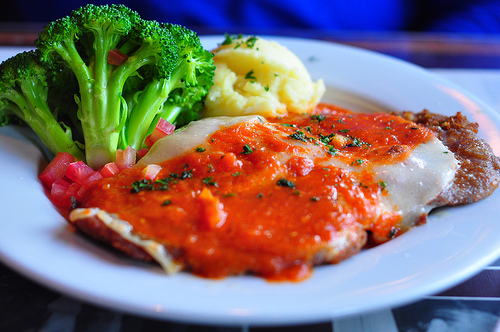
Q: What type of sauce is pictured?
A: The sauce is a dressing.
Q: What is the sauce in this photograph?
A: The sauce is a dressing.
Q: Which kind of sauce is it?
A: The sauce is a dressing.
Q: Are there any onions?
A: Yes, there are onions.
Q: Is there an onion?
A: Yes, there are onions.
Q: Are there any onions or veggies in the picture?
A: Yes, there are onions.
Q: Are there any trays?
A: No, there are no trays.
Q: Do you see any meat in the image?
A: Yes, there is meat.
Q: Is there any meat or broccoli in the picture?
A: Yes, there is meat.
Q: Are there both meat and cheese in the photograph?
A: Yes, there are both meat and cheese.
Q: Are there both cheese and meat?
A: Yes, there are both meat and cheese.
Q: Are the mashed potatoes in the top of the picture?
A: Yes, the mashed potatoes are in the top of the image.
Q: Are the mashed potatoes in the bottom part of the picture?
A: No, the mashed potatoes are in the top of the image.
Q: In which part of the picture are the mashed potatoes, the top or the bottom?
A: The mashed potatoes are in the top of the image.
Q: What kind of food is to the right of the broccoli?
A: The food is mashed potatoes.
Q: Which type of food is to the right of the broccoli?
A: The food is mashed potatoes.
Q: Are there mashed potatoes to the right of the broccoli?
A: Yes, there are mashed potatoes to the right of the broccoli.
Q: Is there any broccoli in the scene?
A: Yes, there is broccoli.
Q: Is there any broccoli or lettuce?
A: Yes, there is broccoli.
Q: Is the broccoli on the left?
A: Yes, the broccoli is on the left of the image.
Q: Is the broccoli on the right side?
A: No, the broccoli is on the left of the image.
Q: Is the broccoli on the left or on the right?
A: The broccoli is on the left of the image.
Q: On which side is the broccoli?
A: The broccoli is on the left of the image.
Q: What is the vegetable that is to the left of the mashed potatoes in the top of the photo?
A: The vegetable is broccoli.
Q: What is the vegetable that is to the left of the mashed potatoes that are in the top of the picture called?
A: The vegetable is broccoli.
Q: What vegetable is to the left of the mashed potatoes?
A: The vegetable is broccoli.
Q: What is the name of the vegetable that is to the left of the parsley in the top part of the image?
A: The vegetable is broccoli.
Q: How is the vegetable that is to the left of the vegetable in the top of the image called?
A: The vegetable is broccoli.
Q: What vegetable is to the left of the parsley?
A: The vegetable is broccoli.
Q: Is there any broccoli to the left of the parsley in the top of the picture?
A: Yes, there is broccoli to the left of the parsley.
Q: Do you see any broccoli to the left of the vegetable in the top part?
A: Yes, there is broccoli to the left of the parsley.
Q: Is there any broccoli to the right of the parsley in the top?
A: No, the broccoli is to the left of the parsley.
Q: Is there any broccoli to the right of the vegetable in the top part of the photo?
A: No, the broccoli is to the left of the parsley.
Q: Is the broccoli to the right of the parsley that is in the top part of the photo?
A: No, the broccoli is to the left of the parsley.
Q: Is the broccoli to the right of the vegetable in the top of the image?
A: No, the broccoli is to the left of the parsley.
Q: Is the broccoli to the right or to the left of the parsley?
A: The broccoli is to the left of the parsley.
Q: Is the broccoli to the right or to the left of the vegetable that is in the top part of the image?
A: The broccoli is to the left of the parsley.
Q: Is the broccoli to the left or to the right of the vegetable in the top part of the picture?
A: The broccoli is to the left of the parsley.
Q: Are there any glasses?
A: No, there are no glasses.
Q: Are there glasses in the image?
A: No, there are no glasses.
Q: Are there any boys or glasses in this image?
A: No, there are no glasses or boys.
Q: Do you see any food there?
A: Yes, there is food.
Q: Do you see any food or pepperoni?
A: Yes, there is food.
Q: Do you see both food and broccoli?
A: Yes, there are both food and broccoli.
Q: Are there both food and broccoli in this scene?
A: Yes, there are both food and broccoli.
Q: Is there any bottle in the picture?
A: No, there are no bottles.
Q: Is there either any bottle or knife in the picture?
A: No, there are no bottles or knives.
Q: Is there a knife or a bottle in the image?
A: No, there are no bottles or knives.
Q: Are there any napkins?
A: No, there are no napkins.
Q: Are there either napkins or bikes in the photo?
A: No, there are no napkins or bikes.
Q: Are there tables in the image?
A: Yes, there is a table.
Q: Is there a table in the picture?
A: Yes, there is a table.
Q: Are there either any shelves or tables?
A: Yes, there is a table.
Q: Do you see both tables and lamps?
A: No, there is a table but no lamps.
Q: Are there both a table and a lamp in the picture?
A: No, there is a table but no lamps.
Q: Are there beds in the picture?
A: No, there are no beds.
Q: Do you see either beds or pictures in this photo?
A: No, there are no beds or pictures.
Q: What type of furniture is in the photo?
A: The furniture is a table.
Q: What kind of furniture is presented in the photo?
A: The furniture is a table.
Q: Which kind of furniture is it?
A: The piece of furniture is a table.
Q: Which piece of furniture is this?
A: This is a table.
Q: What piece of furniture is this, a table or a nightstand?
A: This is a table.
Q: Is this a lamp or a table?
A: This is a table.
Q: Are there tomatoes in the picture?
A: Yes, there are tomatoes.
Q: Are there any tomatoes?
A: Yes, there are tomatoes.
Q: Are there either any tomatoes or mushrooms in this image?
A: Yes, there are tomatoes.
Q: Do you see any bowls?
A: No, there are no bowls.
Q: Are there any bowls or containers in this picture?
A: No, there are no bowls or containers.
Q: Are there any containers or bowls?
A: No, there are no bowls or containers.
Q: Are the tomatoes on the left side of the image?
A: Yes, the tomatoes are on the left of the image.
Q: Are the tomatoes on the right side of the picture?
A: No, the tomatoes are on the left of the image.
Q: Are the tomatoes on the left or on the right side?
A: The tomatoes are on the left of the image.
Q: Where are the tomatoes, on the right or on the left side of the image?
A: The tomatoes are on the left of the image.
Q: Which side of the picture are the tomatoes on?
A: The tomatoes are on the left of the image.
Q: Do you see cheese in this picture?
A: Yes, there is cheese.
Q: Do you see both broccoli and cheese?
A: Yes, there are both cheese and broccoli.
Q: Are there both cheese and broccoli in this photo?
A: Yes, there are both cheese and broccoli.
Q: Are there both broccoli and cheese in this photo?
A: Yes, there are both cheese and broccoli.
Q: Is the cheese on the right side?
A: Yes, the cheese is on the right of the image.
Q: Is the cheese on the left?
A: No, the cheese is on the right of the image.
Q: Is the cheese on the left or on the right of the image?
A: The cheese is on the right of the image.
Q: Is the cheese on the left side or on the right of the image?
A: The cheese is on the right of the image.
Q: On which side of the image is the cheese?
A: The cheese is on the right of the image.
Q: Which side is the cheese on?
A: The cheese is on the right of the image.